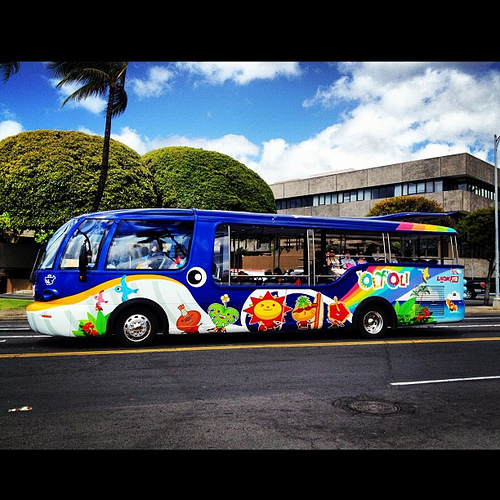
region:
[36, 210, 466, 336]
colorful bus on the street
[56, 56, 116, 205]
palm tree behind the bus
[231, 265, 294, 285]
people riding a bus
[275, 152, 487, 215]
building with windows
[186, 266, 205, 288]
black and white eyeball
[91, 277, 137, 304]
pink and blue birds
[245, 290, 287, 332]
red and yellow sunshine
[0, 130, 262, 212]
round green trees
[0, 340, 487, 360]
yellow center line of the street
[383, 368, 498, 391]
white line on the street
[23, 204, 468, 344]
The bus is blue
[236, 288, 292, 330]
Red and yellow sun character on side of bus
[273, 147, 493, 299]
Grey building behind bus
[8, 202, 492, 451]
The bus is on the street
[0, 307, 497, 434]
Yellow and white lines on the street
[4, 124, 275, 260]
Round green trees behind the bus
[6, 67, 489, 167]
The clouds are white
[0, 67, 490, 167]
Blue sky with clouds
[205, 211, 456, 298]
The bus has large open windows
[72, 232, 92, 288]
The bus has a black mirror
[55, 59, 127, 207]
palm tree is blowing in the wind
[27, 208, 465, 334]
brightly painted passenger bus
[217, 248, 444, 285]
passenger seating on the bus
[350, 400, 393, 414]
manhole on the street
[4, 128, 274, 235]
large manicured bushes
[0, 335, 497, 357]
double yellow line on the street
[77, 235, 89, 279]
side mirror is black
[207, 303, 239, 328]
green heart with a face painted in it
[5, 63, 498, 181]
scattered clouds in the sky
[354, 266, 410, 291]
colorful words on the side of the bus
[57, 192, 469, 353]
colorful passenger bus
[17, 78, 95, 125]
white clouds in blue sky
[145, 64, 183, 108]
white clouds in blue sky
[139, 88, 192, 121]
white clouds in blue sky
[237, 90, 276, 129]
white clouds in blue sky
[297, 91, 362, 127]
white clouds in blue sky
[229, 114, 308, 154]
white clouds in blue sky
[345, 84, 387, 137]
white clouds in blue sky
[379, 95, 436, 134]
white clouds in blue sky